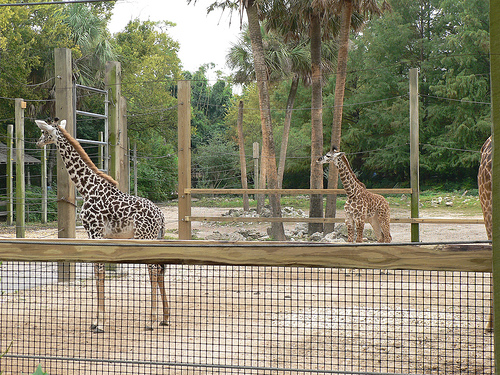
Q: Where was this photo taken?
A: At the zoo.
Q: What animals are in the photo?
A: Giraffe.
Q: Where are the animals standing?
A: In a pen.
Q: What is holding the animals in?
A: A fence.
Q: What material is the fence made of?
A: Wood.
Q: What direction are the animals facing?
A: Left.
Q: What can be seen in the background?
A: Trees.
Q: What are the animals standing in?
A: The dirt.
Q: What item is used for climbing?
A: The ladder.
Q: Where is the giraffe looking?
A: The giraffe is looking left.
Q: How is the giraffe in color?
A: Brown and white.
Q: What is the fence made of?
A: Fence is made of wire.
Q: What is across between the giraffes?
A: Two wooden beams.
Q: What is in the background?
A: Dense vegetation.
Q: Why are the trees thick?
A: The trees are filled with green leaves.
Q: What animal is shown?
A: Giraffes.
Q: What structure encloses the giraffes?
A: Fence.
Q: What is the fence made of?
A: Metal and wood.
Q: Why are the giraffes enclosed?
A: For their protection.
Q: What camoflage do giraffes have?
A: Tan with brown spots.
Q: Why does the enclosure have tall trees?
A: For shade.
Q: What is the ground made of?
A: Soft dirt.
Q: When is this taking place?
A: Daytime.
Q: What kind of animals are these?
A: Giraffes.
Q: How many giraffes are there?
A: Three.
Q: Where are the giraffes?
A: Wood fence enclosure.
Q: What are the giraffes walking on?
A: Dirt ground.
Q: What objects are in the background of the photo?
A: Trees and brush.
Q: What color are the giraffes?
A: Brown and tan.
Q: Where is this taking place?
A: In a zoo.